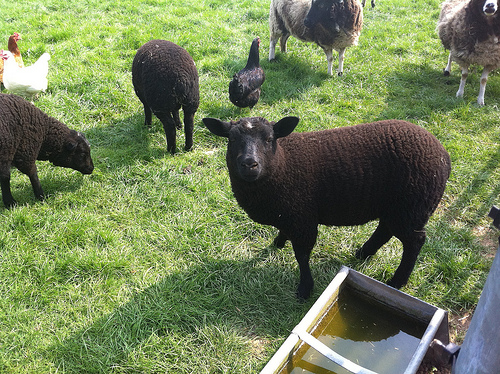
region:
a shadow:
[115, 292, 190, 341]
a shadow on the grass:
[117, 299, 178, 338]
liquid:
[327, 311, 393, 351]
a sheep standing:
[202, 116, 480, 265]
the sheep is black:
[198, 117, 457, 237]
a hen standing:
[216, 34, 280, 114]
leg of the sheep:
[292, 231, 314, 293]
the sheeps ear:
[277, 114, 302, 134]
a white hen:
[2, 50, 56, 89]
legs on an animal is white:
[456, 63, 493, 107]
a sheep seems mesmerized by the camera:
[198, 110, 302, 190]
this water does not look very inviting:
[257, 260, 449, 371]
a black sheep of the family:
[200, 111, 459, 303]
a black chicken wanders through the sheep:
[223, 32, 271, 112]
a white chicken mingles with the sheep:
[0, 42, 52, 92]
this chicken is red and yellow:
[1, 28, 26, 85]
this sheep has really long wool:
[435, 0, 499, 107]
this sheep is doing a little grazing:
[1, 91, 100, 214]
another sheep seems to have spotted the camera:
[432, 0, 499, 110]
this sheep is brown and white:
[264, 0, 382, 82]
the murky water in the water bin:
[274, 283, 427, 372]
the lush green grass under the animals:
[0, 0, 498, 369]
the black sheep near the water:
[202, 114, 452, 301]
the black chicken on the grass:
[230, 36, 262, 119]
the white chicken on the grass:
[0, 51, 47, 106]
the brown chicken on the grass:
[0, 33, 23, 84]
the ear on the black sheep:
[273, 115, 298, 141]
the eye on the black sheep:
[263, 136, 273, 145]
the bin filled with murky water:
[253, 260, 450, 372]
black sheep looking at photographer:
[202, 108, 451, 287]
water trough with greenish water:
[249, 254, 446, 371]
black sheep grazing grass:
[0, 93, 98, 217]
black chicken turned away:
[218, 28, 284, 115]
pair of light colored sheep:
[258, 0, 498, 110]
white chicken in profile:
[0, 47, 58, 96]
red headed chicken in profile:
[2, 28, 29, 60]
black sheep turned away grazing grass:
[123, 28, 209, 169]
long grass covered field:
[11, 204, 206, 363]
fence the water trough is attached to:
[256, 259, 496, 369]